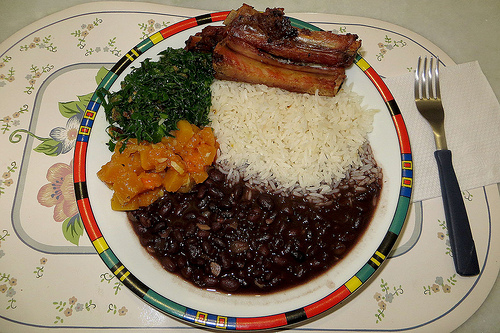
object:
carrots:
[97, 123, 220, 211]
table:
[420, 12, 460, 49]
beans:
[126, 169, 382, 296]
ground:
[417, 157, 454, 182]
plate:
[70, 6, 417, 331]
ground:
[390, 198, 425, 241]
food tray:
[0, 0, 500, 332]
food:
[97, 4, 390, 299]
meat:
[182, 26, 346, 98]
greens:
[98, 48, 222, 144]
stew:
[138, 156, 375, 293]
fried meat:
[222, 2, 361, 66]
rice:
[209, 79, 383, 205]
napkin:
[385, 60, 499, 199]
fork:
[413, 56, 480, 277]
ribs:
[211, 3, 361, 65]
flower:
[36, 163, 79, 223]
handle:
[432, 149, 480, 277]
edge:
[72, 118, 91, 235]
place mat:
[0, 6, 79, 328]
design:
[9, 66, 108, 251]